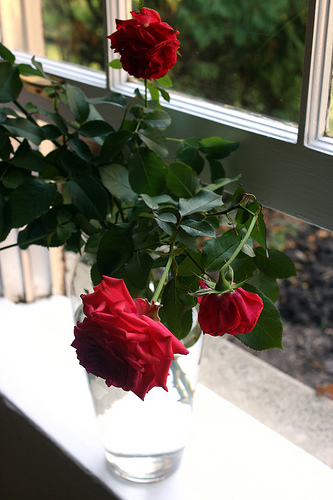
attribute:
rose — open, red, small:
[111, 11, 188, 83]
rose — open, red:
[68, 280, 181, 394]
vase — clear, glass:
[71, 237, 207, 486]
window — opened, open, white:
[4, 2, 328, 466]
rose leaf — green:
[164, 161, 196, 201]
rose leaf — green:
[97, 163, 140, 201]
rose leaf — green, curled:
[64, 81, 90, 123]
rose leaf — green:
[200, 135, 239, 159]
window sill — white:
[5, 286, 332, 499]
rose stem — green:
[169, 355, 194, 410]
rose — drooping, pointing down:
[196, 280, 261, 333]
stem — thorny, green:
[151, 225, 181, 302]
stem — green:
[212, 203, 267, 290]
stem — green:
[119, 76, 155, 163]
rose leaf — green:
[10, 182, 65, 224]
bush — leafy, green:
[40, 2, 313, 133]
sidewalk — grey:
[65, 249, 332, 468]